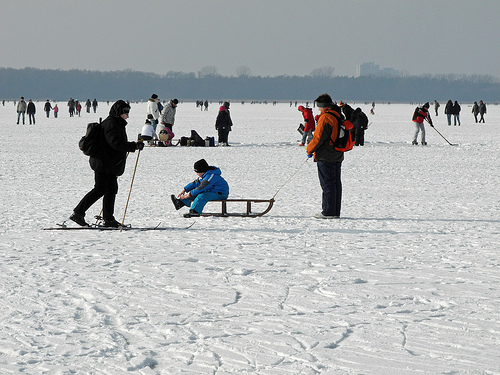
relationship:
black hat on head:
[194, 159, 211, 166] [189, 152, 220, 179]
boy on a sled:
[168, 158, 230, 217] [187, 196, 278, 220]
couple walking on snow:
[16, 95, 37, 124] [0, 100, 500, 373]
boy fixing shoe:
[172, 158, 229, 218] [168, 192, 184, 210]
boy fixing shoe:
[172, 158, 229, 218] [184, 210, 201, 219]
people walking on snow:
[11, 60, 493, 245] [379, 167, 493, 252]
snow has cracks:
[0, 100, 500, 373] [170, 285, 336, 367]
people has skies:
[68, 99, 145, 230] [0, 95, 495, 373]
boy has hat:
[172, 158, 229, 218] [192, 157, 208, 170]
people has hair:
[68, 99, 145, 230] [107, 97, 125, 122]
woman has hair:
[304, 92, 353, 222] [311, 93, 333, 103]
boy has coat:
[172, 158, 229, 218] [182, 166, 229, 215]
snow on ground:
[0, 100, 500, 373] [0, 98, 497, 373]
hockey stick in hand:
[120, 138, 145, 234] [132, 139, 144, 150]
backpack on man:
[63, 119, 127, 177] [306, 83, 386, 228]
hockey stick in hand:
[121, 132, 157, 224] [133, 139, 146, 151]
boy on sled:
[168, 158, 230, 217] [191, 192, 273, 219]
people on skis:
[68, 99, 145, 230] [46, 203, 176, 265]